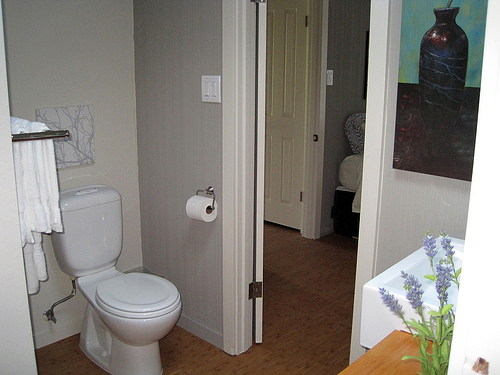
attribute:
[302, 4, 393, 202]
wall — gray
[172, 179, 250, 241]
holder — hanging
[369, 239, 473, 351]
arrangement — purple, floral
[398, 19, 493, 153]
artwork — hanging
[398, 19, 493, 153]
wall — bathroom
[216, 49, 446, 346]
doorway — bathroom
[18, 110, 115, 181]
artwork — small, piece, square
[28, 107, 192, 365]
stool — toilet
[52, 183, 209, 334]
toilet — white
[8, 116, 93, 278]
towels — white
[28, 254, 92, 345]
valve — water shut off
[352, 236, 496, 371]
table — brown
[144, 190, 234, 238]
paper — roll, toilet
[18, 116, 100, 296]
towels — white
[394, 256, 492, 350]
flowers — purple 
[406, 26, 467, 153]
vase — brown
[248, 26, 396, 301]
door — open, bathroom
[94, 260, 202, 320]
seat — closed, toilet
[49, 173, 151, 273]
tank — toilet, small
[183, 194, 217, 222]
tissue — white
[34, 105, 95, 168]
picture — gray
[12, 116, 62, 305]
towel — white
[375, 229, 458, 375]
flowers — purple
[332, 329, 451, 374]
table — wooden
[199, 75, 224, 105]
light switch — white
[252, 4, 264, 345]
door — open, white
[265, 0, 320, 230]
door — closed, white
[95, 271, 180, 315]
lid — down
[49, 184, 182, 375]
toilet — white